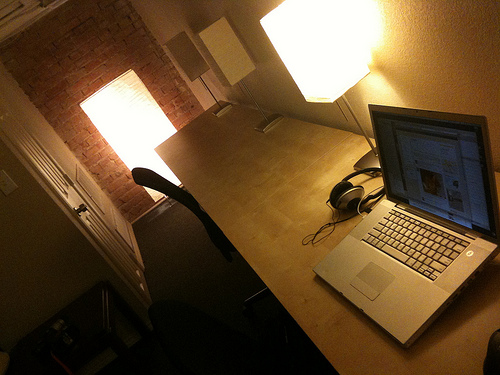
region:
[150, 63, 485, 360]
long tan table against wall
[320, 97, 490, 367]
open laptop on table surface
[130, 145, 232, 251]
curved back of black chair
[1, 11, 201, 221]
brick wall with bright panel of light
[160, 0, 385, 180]
three table lamps with rectangular shades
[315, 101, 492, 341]
blue screen over silver keyboards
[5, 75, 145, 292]
white wall with paneled door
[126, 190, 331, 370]
smooth black flooring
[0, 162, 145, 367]
container at bottom of wall in dark area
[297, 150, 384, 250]
curved headphone and thin looped wires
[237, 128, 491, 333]
a computer on a table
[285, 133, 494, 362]
a laptop on a table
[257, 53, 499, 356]
a silver laptop on table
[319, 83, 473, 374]
an open laptop on table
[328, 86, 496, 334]
a silver open laptop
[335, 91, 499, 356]
a silver open laptop on table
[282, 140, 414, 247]
headphone on a table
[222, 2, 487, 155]
lights on a wall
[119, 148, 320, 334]
a chair under the desk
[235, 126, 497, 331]
a table with a laptop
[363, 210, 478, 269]
keyboard on the computer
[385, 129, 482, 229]
moniter has information on screen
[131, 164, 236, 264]
chair next to desk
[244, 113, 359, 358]
desk that computer is on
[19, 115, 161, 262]
door to room is closed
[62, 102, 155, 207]
brick on the wall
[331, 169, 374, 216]
headphones next to computer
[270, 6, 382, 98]
light is bright and on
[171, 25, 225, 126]
second light is turned off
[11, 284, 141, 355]
desk against the wall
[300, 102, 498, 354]
open laptop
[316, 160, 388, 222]
large over the ear headphones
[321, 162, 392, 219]
over the head headphones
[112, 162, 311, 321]
black rolling office chair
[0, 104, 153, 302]
white closed door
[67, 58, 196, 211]
very brightly lit doorway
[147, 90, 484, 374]
long wooden table with three lamps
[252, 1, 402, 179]
desk lamp lit up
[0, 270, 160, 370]
short wooden end table against a wall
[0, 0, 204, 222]
brick wall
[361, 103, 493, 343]
lap top on a desk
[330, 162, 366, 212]
head phones on a desk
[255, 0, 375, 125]
lamp on a table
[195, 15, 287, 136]
lamp on a table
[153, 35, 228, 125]
lamp on a desk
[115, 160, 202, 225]
chair next to desk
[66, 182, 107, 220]
knob on a door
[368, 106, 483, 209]
screen on a laptop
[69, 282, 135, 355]
table next to wall